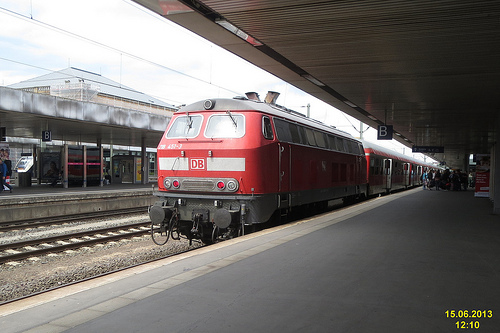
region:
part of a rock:
[74, 265, 75, 268]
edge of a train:
[260, 157, 262, 171]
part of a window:
[73, 148, 81, 167]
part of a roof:
[343, 58, 370, 74]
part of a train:
[306, 147, 316, 162]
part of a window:
[211, 140, 226, 166]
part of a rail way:
[48, 236, 65, 261]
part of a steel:
[218, 193, 226, 239]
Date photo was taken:
[439, 308, 496, 321]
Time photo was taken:
[449, 317, 490, 331]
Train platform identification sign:
[367, 122, 397, 144]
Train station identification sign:
[406, 141, 446, 156]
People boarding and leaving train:
[419, 165, 484, 192]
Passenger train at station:
[141, 86, 458, 246]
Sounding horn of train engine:
[200, 98, 218, 113]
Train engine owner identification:
[186, 159, 213, 172]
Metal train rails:
[1, 211, 152, 265]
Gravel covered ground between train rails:
[0, 219, 205, 303]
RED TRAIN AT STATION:
[146, 53, 428, 259]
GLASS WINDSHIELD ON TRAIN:
[197, 107, 254, 145]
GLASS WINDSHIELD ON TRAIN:
[172, 112, 200, 129]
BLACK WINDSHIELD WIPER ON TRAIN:
[224, 113, 244, 128]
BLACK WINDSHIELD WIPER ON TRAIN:
[183, 106, 203, 133]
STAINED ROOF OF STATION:
[18, 91, 183, 129]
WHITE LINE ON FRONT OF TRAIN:
[154, 152, 286, 174]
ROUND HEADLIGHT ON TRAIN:
[229, 177, 236, 191]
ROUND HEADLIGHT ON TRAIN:
[162, 177, 173, 193]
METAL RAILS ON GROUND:
[47, 228, 119, 268]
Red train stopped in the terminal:
[148, 90, 449, 241]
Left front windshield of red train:
[203, 110, 244, 136]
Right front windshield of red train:
[165, 113, 203, 138]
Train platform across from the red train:
[0, 183, 160, 228]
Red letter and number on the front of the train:
[187, 155, 205, 170]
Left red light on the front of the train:
[215, 180, 225, 188]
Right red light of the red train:
[170, 178, 177, 185]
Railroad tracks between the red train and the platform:
[0, 198, 160, 259]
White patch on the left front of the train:
[205, 155, 245, 171]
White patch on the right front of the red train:
[158, 157, 188, 171]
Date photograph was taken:
[439, 306, 496, 321]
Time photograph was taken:
[452, 318, 485, 330]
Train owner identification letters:
[185, 156, 209, 171]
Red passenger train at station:
[134, 91, 441, 248]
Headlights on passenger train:
[157, 174, 239, 193]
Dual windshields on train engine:
[162, 111, 247, 146]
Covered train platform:
[120, 0, 497, 331]